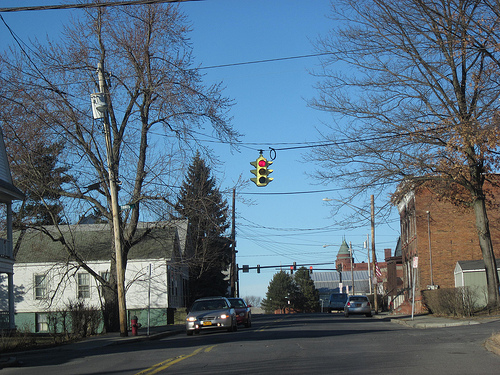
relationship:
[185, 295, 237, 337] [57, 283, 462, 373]
car on road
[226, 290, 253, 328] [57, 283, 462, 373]
car on road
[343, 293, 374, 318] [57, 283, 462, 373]
car on road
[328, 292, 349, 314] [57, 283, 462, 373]
car on road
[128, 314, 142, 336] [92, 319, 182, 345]
hydrant on sidewalk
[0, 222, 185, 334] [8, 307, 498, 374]
building on side of road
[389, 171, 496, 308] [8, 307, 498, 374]
building on side of road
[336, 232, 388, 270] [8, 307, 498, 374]
building on side of road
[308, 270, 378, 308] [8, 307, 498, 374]
building on side of road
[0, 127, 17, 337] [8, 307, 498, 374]
building on side of road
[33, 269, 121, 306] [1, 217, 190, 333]
windows on house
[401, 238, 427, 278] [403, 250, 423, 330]
sign on a stick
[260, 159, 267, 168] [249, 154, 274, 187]
light on a light box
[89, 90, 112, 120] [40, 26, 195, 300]
transfomer on power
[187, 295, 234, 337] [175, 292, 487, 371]
car at intersection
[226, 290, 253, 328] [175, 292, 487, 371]
car at intersection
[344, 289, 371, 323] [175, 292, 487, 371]
car at intersection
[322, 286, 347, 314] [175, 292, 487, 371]
car at intersection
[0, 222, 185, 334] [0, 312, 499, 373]
building by road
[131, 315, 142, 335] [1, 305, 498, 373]
hydrant by street